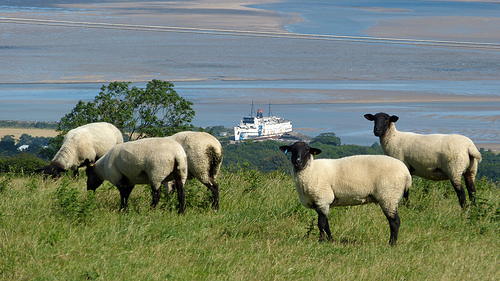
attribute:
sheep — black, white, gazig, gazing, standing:
[276, 135, 417, 250]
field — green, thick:
[5, 119, 498, 278]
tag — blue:
[282, 147, 290, 153]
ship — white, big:
[228, 94, 299, 142]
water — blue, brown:
[0, 4, 497, 149]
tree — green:
[46, 73, 199, 150]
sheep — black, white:
[79, 132, 194, 219]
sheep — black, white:
[358, 102, 487, 216]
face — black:
[370, 105, 394, 139]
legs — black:
[308, 209, 414, 255]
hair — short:
[470, 145, 486, 164]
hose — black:
[290, 152, 301, 163]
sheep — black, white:
[34, 116, 128, 197]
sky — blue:
[317, 12, 346, 37]